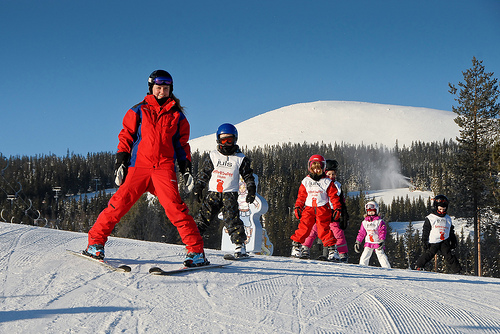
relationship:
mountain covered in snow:
[261, 98, 430, 138] [304, 110, 397, 136]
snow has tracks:
[304, 110, 397, 136] [301, 271, 497, 331]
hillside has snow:
[186, 100, 498, 150] [304, 110, 397, 136]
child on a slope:
[194, 123, 256, 259] [2, 219, 500, 333]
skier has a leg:
[87, 67, 211, 269] [154, 183, 204, 252]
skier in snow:
[87, 67, 211, 269] [304, 110, 397, 136]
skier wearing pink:
[87, 67, 211, 269] [304, 221, 349, 254]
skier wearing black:
[87, 67, 211, 269] [197, 148, 257, 201]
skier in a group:
[87, 67, 211, 269] [85, 70, 465, 275]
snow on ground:
[304, 110, 397, 136] [4, 220, 500, 333]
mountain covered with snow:
[261, 98, 430, 138] [304, 110, 397, 136]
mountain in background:
[261, 98, 430, 138] [186, 2, 499, 123]